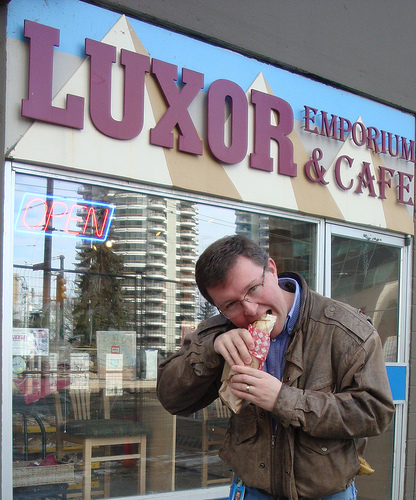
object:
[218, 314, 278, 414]
pita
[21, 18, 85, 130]
letters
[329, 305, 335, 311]
button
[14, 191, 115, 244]
open sign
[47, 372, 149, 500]
chair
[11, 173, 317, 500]
mirror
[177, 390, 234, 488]
chair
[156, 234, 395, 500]
man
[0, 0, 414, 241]
sign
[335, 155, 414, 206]
cafe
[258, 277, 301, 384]
shirt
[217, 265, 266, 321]
glasses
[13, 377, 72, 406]
tablecloth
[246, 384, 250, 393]
gold band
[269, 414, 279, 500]
zipper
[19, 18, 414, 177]
luxor emporium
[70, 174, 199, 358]
reflections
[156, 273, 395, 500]
jacket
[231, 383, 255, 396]
finger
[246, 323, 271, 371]
wrapping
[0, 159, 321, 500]
window